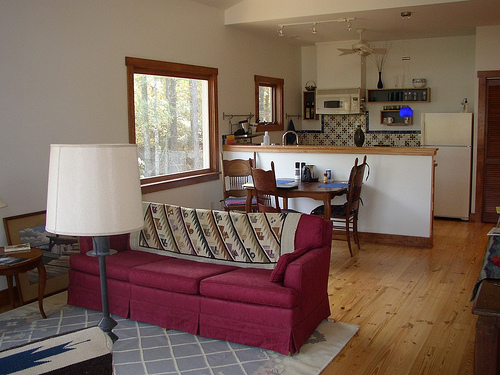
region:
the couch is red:
[51, 166, 321, 365]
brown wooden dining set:
[199, 146, 389, 271]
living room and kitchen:
[16, 12, 471, 364]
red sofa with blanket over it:
[65, 182, 337, 347]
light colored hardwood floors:
[235, 175, 496, 370]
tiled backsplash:
[281, 110, 421, 146]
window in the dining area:
[128, 62, 223, 183]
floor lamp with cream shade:
[37, 133, 162, 368]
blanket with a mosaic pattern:
[0, 315, 110, 371]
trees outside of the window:
[136, 75, 206, 166]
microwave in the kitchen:
[315, 90, 357, 115]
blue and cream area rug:
[0, 273, 367, 368]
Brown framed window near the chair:
[124, 54, 221, 193]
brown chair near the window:
[216, 150, 264, 212]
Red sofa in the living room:
[65, 200, 334, 359]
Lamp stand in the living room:
[43, 141, 145, 373]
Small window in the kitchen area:
[248, 72, 284, 128]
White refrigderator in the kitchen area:
[421, 111, 476, 220]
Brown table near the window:
[241, 175, 353, 214]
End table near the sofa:
[0, 239, 47, 321]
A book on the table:
[2, 241, 31, 251]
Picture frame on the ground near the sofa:
[3, 208, 80, 306]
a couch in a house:
[99, 188, 361, 351]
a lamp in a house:
[17, 134, 181, 326]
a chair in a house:
[289, 151, 416, 264]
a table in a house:
[216, 154, 353, 239]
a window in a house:
[119, 48, 263, 165]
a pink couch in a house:
[144, 163, 338, 358]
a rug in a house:
[0, 203, 407, 359]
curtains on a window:
[136, 56, 248, 166]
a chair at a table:
[228, 148, 307, 204]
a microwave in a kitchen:
[273, 78, 391, 132]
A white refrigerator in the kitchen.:
[420, 109, 477, 222]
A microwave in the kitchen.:
[313, 92, 361, 117]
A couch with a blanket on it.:
[64, 200, 333, 357]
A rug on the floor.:
[0, 283, 362, 373]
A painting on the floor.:
[1, 208, 76, 305]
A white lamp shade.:
[43, 142, 148, 238]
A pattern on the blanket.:
[136, 203, 287, 266]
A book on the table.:
[3, 241, 34, 253]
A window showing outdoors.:
[121, 55, 221, 191]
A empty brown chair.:
[218, 149, 257, 208]